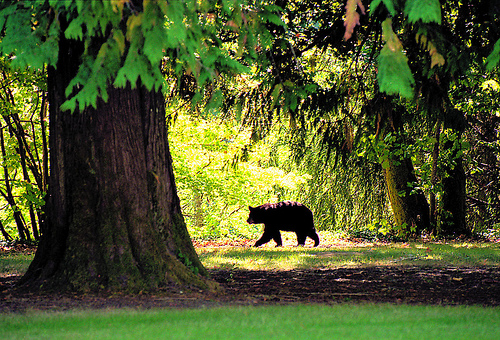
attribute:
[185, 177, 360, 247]
nature — setting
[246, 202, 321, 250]
bear — here, lonely, hunting, awake, walking, black, hungry, exposed, searching, big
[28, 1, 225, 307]
tree — large, dying, growing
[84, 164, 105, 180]
moss — green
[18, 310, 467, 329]
grass — green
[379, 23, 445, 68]
leaves — orange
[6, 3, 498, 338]
forest — here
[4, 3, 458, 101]
foliage — green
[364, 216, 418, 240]
plant — growing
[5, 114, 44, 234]
tree — small